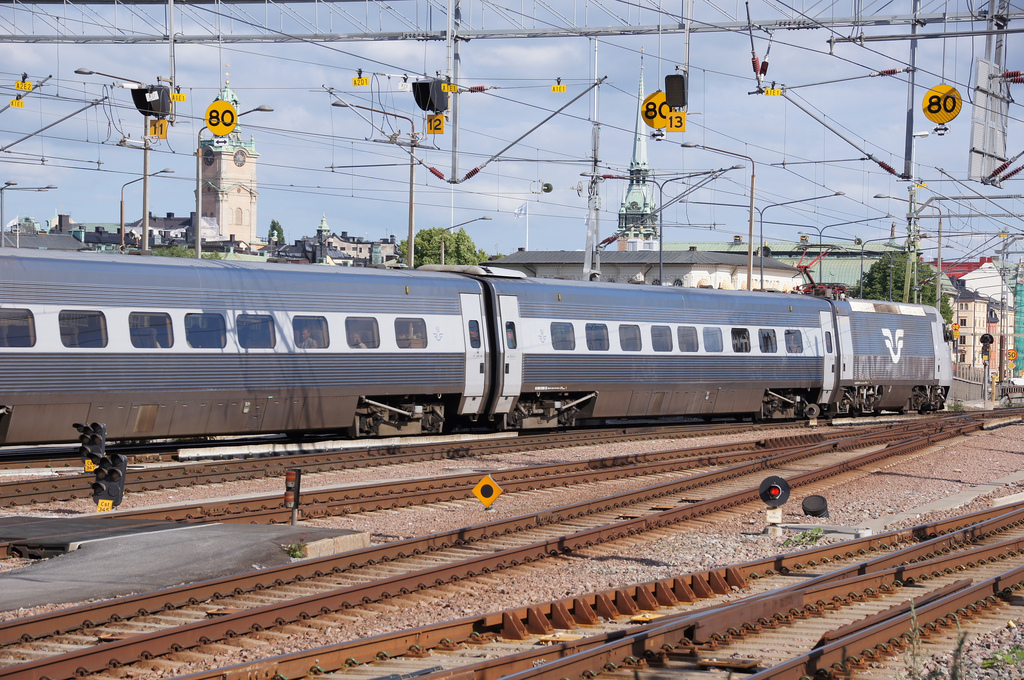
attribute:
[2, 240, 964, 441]
train — silver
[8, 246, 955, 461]
train — silver 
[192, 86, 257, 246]
building — tall 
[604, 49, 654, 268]
building — tall 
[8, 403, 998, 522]
track — rusty 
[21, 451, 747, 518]
gravel — tan 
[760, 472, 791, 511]
light — red 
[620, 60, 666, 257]
steeple — blue 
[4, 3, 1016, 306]
sky — blue 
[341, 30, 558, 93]
cloud — white 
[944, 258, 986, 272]
roof — red 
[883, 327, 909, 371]
logo — white 